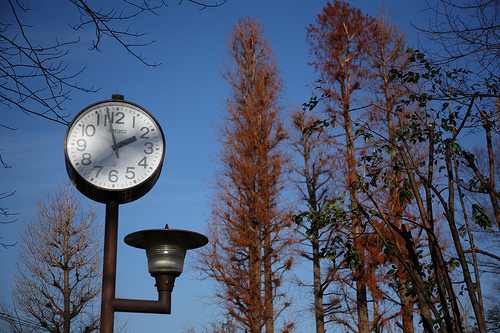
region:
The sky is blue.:
[175, 55, 210, 117]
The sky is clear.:
[174, 55, 211, 128]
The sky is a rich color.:
[176, 68, 210, 157]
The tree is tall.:
[208, 13, 288, 330]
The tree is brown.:
[213, 15, 284, 331]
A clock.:
[59, 95, 171, 205]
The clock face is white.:
[61, 95, 171, 209]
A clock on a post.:
[52, 90, 198, 332]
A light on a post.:
[121, 214, 219, 297]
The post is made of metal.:
[86, 199, 173, 331]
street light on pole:
[120, 218, 212, 314]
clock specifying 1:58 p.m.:
[55, 87, 171, 216]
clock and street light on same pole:
[57, 78, 210, 331]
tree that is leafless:
[13, 189, 99, 331]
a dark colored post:
[97, 205, 130, 332]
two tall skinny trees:
[210, 15, 291, 332]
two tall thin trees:
[207, 12, 294, 332]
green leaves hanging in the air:
[297, 87, 324, 119]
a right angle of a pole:
[145, 292, 180, 319]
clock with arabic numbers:
[60, 76, 173, 209]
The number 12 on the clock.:
[107, 107, 128, 127]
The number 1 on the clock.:
[129, 112, 140, 126]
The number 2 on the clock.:
[137, 121, 153, 137]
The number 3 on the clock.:
[143, 140, 156, 156]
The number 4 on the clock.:
[132, 155, 153, 173]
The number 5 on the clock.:
[122, 163, 139, 180]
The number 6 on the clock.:
[107, 167, 118, 179]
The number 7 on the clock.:
[94, 158, 106, 176]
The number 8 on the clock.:
[76, 152, 91, 170]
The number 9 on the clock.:
[72, 134, 86, 149]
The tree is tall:
[203, 12, 312, 329]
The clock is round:
[49, 82, 184, 231]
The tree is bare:
[18, 183, 101, 329]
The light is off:
[123, 215, 217, 327]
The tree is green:
[278, 86, 393, 328]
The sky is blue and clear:
[140, 40, 265, 181]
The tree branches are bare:
[10, 15, 87, 165]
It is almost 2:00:
[83, 71, 184, 192]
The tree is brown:
[220, 55, 275, 255]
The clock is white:
[52, 90, 207, 239]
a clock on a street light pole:
[63, 91, 165, 201]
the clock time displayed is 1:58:
[66, 103, 162, 188]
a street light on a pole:
[100, 223, 208, 331]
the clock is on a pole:
[64, 92, 166, 332]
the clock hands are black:
[104, 106, 137, 161]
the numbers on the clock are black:
[92, 165, 104, 179]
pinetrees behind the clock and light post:
[211, 1, 498, 332]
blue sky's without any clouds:
[1, 0, 228, 87]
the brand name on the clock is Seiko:
[106, 126, 129, 134]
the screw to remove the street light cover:
[163, 222, 170, 229]